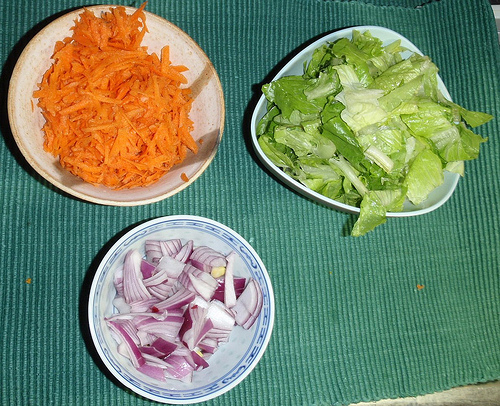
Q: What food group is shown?
A: Vegetables.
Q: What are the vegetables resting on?
A: Plates.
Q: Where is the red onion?
A: In the plate.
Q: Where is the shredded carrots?
A: In a plate.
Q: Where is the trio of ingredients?
A: In the plates.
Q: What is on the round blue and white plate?
A: Chopped onion.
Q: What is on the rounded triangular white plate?
A: Chopped lettuce.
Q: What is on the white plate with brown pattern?
A: Shredded carrots.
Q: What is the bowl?
A: Chopped onions.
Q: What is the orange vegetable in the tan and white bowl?
A: Shredded carrots.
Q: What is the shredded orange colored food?
A: Carrots.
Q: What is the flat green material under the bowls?
A: A placemat.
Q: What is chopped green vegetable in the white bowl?
A: Lettuce.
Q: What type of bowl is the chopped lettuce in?
A: A triangular bowl.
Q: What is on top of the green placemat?
A: Three bowls of vegetables.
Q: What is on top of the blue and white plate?
A: Chopped red onions.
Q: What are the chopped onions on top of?
A: Blue and white plate.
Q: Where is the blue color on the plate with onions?
A: Around the edges.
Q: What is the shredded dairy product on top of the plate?
A: Orange cheese.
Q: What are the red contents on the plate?
A: Cheddar cheese.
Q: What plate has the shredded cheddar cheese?
A: The white plate.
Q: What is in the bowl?
A: Lettuce.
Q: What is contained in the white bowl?
A: Lettuce.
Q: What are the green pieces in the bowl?
A: Lettuce.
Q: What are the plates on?
A: On a table.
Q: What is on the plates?
A: Food.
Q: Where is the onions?
A: On the plate.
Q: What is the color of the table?
A: Green.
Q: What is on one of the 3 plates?
A: Cheese.